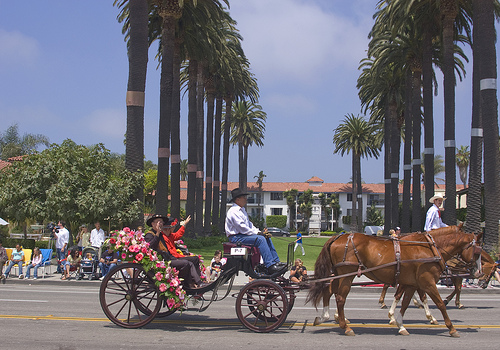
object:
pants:
[225, 234, 279, 268]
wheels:
[235, 276, 298, 334]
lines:
[0, 314, 499, 329]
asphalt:
[0, 286, 498, 347]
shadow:
[103, 307, 309, 335]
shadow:
[312, 317, 478, 335]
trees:
[329, 0, 498, 250]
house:
[147, 176, 468, 229]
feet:
[267, 264, 287, 275]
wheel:
[97, 263, 163, 329]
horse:
[302, 228, 484, 339]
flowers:
[108, 225, 190, 314]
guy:
[224, 187, 288, 275]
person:
[49, 221, 70, 273]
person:
[80, 225, 91, 250]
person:
[89, 222, 106, 259]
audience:
[0, 220, 120, 281]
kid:
[2, 244, 25, 280]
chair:
[6, 248, 31, 278]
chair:
[27, 249, 53, 279]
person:
[289, 258, 308, 284]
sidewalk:
[0, 265, 498, 295]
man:
[424, 193, 450, 232]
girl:
[24, 247, 43, 280]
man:
[143, 213, 207, 289]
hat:
[146, 213, 169, 227]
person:
[161, 214, 206, 282]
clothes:
[161, 225, 186, 258]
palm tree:
[112, 0, 150, 232]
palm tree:
[155, 0, 178, 217]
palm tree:
[169, 2, 180, 218]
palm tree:
[184, 0, 199, 232]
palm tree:
[194, 59, 204, 236]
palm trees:
[218, 97, 266, 212]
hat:
[429, 193, 447, 203]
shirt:
[423, 204, 449, 231]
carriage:
[97, 229, 499, 337]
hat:
[228, 188, 252, 203]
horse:
[441, 246, 499, 309]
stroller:
[77, 246, 101, 281]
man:
[294, 229, 307, 257]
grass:
[308, 240, 319, 253]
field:
[269, 225, 339, 268]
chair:
[134, 235, 195, 287]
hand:
[151, 217, 165, 232]